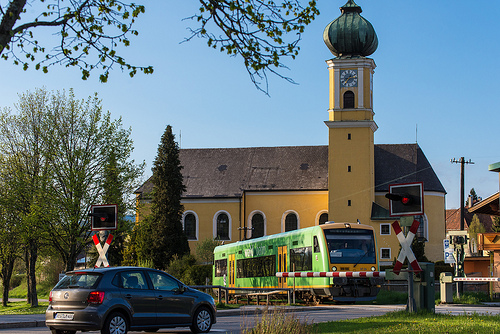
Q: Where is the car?
A: Behind the railroad crossing.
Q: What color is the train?
A: Green and yellow.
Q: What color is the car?
A: Dark gray.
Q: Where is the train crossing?
A: In front of a church.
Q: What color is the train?
A: Green.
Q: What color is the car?
A: Gray.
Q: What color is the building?
A: Yellow.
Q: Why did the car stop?
A: Train is approaching.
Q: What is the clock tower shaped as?
A: An onion.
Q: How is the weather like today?
A: Clear and sunny.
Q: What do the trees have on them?
A: Leaves.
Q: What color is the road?
A: Black.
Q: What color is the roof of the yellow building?
A: Brown.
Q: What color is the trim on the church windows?
A: White.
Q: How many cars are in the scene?
A: One.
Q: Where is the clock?
A: On the tower.